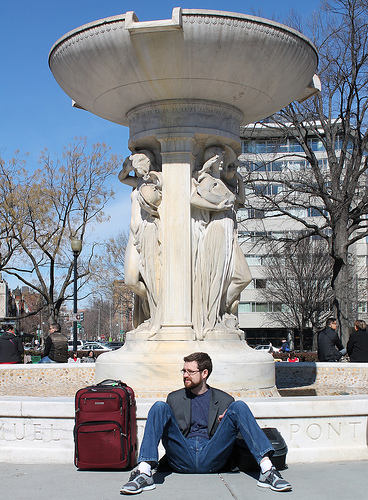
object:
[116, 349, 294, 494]
man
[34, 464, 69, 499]
ground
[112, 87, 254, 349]
statue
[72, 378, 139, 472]
luggage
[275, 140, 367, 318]
tree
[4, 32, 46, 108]
sky